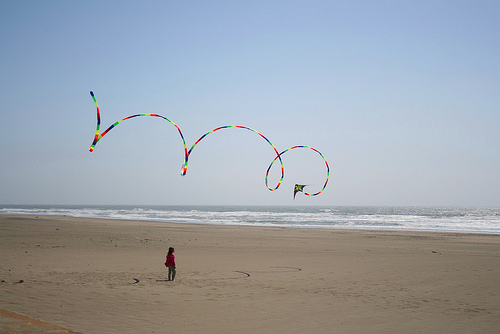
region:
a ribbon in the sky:
[61, 80, 345, 205]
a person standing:
[159, 241, 184, 286]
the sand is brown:
[297, 237, 467, 330]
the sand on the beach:
[283, 231, 435, 331]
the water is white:
[353, 210, 433, 231]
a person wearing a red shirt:
[165, 252, 176, 264]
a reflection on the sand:
[231, 249, 319, 281]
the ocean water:
[358, 203, 468, 231]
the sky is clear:
[218, 23, 415, 118]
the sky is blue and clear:
[237, 18, 402, 100]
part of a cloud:
[437, 185, 457, 206]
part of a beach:
[337, 201, 351, 233]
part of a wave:
[358, 218, 371, 238]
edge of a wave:
[364, 185, 379, 210]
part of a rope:
[291, 145, 331, 170]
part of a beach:
[186, 283, 189, 289]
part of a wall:
[365, 210, 371, 224]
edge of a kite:
[285, 176, 300, 183]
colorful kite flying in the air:
[75, 68, 338, 221]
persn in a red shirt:
[159, 239, 183, 288]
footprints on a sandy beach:
[28, 242, 105, 297]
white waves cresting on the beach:
[325, 203, 433, 224]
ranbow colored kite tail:
[76, 68, 334, 213]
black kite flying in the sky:
[292, 181, 311, 200]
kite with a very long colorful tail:
[60, 70, 347, 224]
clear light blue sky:
[283, 16, 400, 111]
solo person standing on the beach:
[136, 231, 218, 295]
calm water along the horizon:
[346, 198, 495, 213]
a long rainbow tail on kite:
[51, 75, 361, 247]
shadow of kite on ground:
[98, 242, 319, 302]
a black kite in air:
[293, 180, 310, 198]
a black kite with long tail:
[286, 177, 319, 203]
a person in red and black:
[148, 225, 198, 293]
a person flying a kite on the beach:
[136, 223, 226, 290]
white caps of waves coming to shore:
[79, 181, 491, 243]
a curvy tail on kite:
[73, 92, 326, 199]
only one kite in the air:
[70, 90, 364, 220]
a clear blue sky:
[8, 7, 490, 228]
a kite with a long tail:
[77, 77, 352, 202]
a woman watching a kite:
[67, 80, 344, 284]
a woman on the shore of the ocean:
[155, 200, 494, 326]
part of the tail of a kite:
[81, 90, 104, 123]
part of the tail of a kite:
[106, 102, 188, 175]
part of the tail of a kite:
[183, 104, 283, 203]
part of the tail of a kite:
[291, 139, 346, 174]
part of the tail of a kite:
[71, 75, 173, 170]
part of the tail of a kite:
[86, 80, 251, 186]